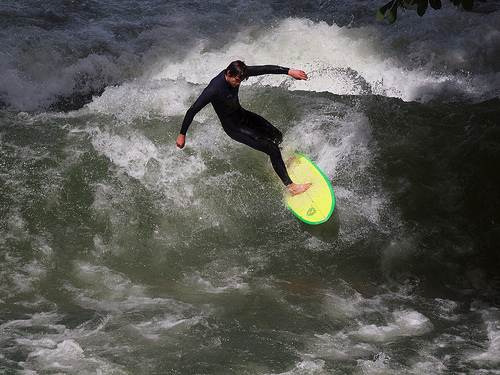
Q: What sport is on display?
A: Surfing.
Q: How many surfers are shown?
A: One.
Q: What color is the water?
A: Green.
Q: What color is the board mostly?
A: Yellow.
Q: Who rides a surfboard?
A: Surfer.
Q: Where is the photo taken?
A: Ocean.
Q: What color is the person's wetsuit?
A: Black.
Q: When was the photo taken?
A: Daytime.